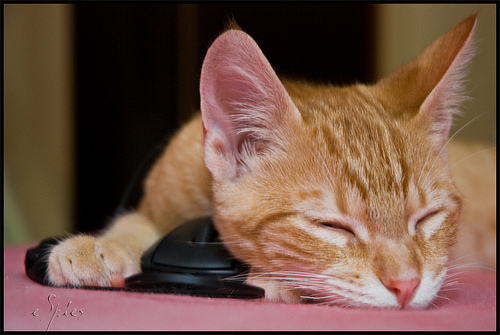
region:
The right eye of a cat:
[299, 206, 366, 253]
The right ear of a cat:
[192, 17, 307, 185]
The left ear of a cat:
[365, 5, 487, 155]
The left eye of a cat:
[402, 197, 458, 245]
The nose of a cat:
[375, 267, 427, 312]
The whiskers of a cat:
[237, 263, 368, 315]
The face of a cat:
[190, 4, 487, 320]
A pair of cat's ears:
[192, 8, 491, 185]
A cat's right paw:
[35, 203, 180, 299]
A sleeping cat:
[42, 8, 486, 315]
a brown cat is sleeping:
[20, 8, 499, 316]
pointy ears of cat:
[178, 10, 490, 153]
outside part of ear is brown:
[361, 8, 491, 126]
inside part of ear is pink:
[192, 18, 304, 163]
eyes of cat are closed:
[292, 189, 461, 244]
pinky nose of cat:
[380, 264, 422, 310]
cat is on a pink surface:
[5, 9, 492, 333]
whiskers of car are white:
[234, 250, 490, 311]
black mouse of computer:
[142, 201, 249, 294]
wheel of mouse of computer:
[181, 210, 221, 256]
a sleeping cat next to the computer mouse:
[24, 9, 489, 324]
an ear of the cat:
[189, 18, 300, 187]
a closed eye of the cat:
[297, 196, 367, 251]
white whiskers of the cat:
[243, 258, 321, 303]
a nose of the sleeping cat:
[382, 268, 424, 308]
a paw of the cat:
[43, 229, 128, 294]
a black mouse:
[139, 217, 245, 292]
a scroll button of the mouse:
[191, 217, 216, 246]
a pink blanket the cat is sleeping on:
[114, 292, 204, 333]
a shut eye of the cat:
[411, 199, 455, 243]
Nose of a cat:
[340, 256, 447, 327]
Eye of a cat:
[297, 205, 367, 253]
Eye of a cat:
[401, 180, 455, 240]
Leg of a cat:
[15, 183, 187, 296]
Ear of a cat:
[191, 12, 312, 194]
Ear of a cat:
[382, 5, 490, 141]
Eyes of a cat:
[299, 180, 461, 247]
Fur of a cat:
[307, 76, 406, 200]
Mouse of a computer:
[136, 203, 264, 295]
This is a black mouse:
[147, 208, 256, 294]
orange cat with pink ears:
[193, 9, 496, 171]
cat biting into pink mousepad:
[278, 269, 465, 321]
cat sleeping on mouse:
[59, 169, 286, 304]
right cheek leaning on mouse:
[121, 198, 299, 306]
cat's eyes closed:
[301, 194, 454, 248]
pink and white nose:
[328, 262, 447, 314]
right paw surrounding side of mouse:
[30, 215, 160, 299]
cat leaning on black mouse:
[15, 8, 485, 318]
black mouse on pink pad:
[9, 243, 499, 333]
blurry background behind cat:
[1, 0, 498, 240]